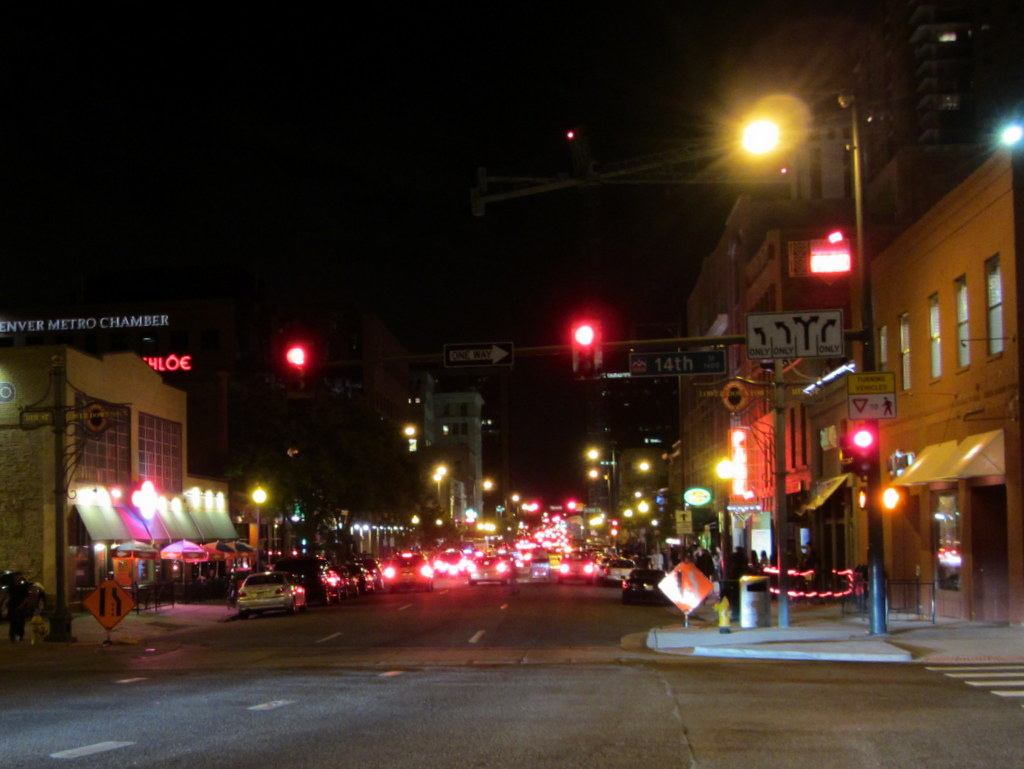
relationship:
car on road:
[613, 553, 681, 621] [5, 553, 682, 766]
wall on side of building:
[653, 22, 1023, 655] [653, 22, 1023, 655]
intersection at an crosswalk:
[100, 619, 696, 709] [100, 619, 696, 709]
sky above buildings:
[29, 13, 656, 317] [9, 47, 1022, 665]